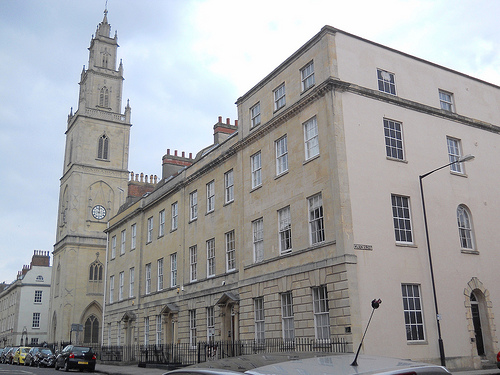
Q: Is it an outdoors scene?
A: Yes, it is outdoors.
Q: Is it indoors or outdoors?
A: It is outdoors.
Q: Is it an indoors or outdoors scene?
A: It is outdoors.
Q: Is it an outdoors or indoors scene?
A: It is outdoors.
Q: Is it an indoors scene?
A: No, it is outdoors.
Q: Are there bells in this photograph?
A: No, there are no bells.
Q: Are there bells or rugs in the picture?
A: No, there are no bells or rugs.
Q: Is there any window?
A: Yes, there is a window.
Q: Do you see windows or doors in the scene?
A: Yes, there is a window.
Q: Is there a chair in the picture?
A: No, there are no chairs.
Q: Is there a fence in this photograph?
A: Yes, there is a fence.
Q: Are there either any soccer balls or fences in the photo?
A: Yes, there is a fence.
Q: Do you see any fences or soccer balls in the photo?
A: Yes, there is a fence.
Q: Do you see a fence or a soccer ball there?
A: Yes, there is a fence.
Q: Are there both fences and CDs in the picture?
A: No, there is a fence but no cds.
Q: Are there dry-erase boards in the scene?
A: No, there are no dry-erase boards.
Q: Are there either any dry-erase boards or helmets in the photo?
A: No, there are no dry-erase boards or helmets.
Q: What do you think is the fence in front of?
A: The fence is in front of the building.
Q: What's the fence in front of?
A: The fence is in front of the building.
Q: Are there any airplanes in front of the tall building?
A: No, there is a fence in front of the building.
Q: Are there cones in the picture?
A: No, there are no cones.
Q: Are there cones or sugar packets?
A: No, there are no cones or sugar packets.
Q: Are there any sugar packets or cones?
A: No, there are no cones or sugar packets.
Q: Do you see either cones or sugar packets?
A: No, there are no cones or sugar packets.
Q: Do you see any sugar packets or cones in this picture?
A: No, there are no cones or sugar packets.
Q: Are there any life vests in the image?
A: No, there are no life vests.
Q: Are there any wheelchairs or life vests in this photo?
A: No, there are no life vests or wheelchairs.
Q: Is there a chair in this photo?
A: No, there are no chairs.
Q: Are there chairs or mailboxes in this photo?
A: No, there are no chairs or mailboxes.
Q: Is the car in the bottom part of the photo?
A: Yes, the car is in the bottom of the image.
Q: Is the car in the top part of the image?
A: No, the car is in the bottom of the image.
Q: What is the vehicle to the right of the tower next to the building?
A: The vehicle is a car.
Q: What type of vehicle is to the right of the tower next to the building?
A: The vehicle is a car.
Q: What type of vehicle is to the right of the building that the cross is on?
A: The vehicle is a car.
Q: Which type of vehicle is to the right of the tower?
A: The vehicle is a car.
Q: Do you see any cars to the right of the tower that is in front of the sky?
A: Yes, there is a car to the right of the tower.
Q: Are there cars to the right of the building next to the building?
A: Yes, there is a car to the right of the tower.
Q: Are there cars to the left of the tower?
A: No, the car is to the right of the tower.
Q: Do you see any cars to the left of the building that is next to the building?
A: No, the car is to the right of the tower.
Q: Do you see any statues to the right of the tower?
A: No, there is a car to the right of the tower.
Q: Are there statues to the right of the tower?
A: No, there is a car to the right of the tower.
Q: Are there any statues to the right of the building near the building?
A: No, there is a car to the right of the tower.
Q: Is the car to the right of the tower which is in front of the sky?
A: Yes, the car is to the right of the tower.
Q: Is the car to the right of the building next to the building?
A: Yes, the car is to the right of the tower.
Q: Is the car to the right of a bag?
A: No, the car is to the right of the tower.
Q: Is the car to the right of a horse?
A: No, the car is to the right of a vehicle.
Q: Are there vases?
A: No, there are no vases.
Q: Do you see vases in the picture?
A: No, there are no vases.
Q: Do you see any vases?
A: No, there are no vases.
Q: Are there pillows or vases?
A: No, there are no vases or pillows.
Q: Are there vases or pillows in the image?
A: No, there are no vases or pillows.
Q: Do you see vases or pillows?
A: No, there are no vases or pillows.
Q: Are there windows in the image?
A: Yes, there is a window.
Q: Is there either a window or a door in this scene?
A: Yes, there is a window.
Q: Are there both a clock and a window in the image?
A: Yes, there are both a window and a clock.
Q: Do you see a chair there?
A: No, there are no chairs.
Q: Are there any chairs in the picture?
A: No, there are no chairs.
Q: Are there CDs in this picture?
A: No, there are no cds.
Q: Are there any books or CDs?
A: No, there are no CDs or books.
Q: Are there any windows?
A: Yes, there is a window.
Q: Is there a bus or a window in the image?
A: Yes, there is a window.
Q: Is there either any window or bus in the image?
A: Yes, there is a window.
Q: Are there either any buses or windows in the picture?
A: Yes, there is a window.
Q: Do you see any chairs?
A: No, there are no chairs.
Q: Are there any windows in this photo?
A: Yes, there is a window.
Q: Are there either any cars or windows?
A: Yes, there is a window.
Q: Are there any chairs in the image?
A: No, there are no chairs.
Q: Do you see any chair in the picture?
A: No, there are no chairs.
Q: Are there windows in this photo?
A: Yes, there is a window.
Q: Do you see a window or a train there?
A: Yes, there is a window.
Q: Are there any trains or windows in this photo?
A: Yes, there is a window.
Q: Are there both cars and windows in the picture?
A: Yes, there are both a window and a car.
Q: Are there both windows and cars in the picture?
A: Yes, there are both a window and a car.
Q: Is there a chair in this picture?
A: No, there are no chairs.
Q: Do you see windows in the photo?
A: Yes, there is a window.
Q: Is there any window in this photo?
A: Yes, there is a window.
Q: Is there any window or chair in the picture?
A: Yes, there is a window.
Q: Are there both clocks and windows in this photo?
A: Yes, there are both a window and a clock.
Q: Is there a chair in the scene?
A: No, there are no chairs.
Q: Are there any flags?
A: No, there are no flags.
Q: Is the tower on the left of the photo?
A: Yes, the tower is on the left of the image.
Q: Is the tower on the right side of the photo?
A: No, the tower is on the left of the image.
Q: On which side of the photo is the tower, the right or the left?
A: The tower is on the left of the image.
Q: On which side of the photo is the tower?
A: The tower is on the left of the image.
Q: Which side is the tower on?
A: The tower is on the left of the image.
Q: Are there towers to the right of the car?
A: No, the tower is to the left of the car.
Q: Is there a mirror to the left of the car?
A: No, there is a tower to the left of the car.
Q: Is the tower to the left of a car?
A: Yes, the tower is to the left of a car.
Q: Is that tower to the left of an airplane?
A: No, the tower is to the left of a car.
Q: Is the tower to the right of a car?
A: No, the tower is to the left of a car.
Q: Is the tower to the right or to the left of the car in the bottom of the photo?
A: The tower is to the left of the car.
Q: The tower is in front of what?
A: The tower is in front of the sky.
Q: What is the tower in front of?
A: The tower is in front of the sky.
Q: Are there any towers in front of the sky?
A: Yes, there is a tower in front of the sky.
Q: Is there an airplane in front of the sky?
A: No, there is a tower in front of the sky.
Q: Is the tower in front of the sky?
A: Yes, the tower is in front of the sky.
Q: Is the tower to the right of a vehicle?
A: Yes, the tower is to the right of a vehicle.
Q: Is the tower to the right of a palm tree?
A: No, the tower is to the right of a vehicle.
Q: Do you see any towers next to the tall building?
A: Yes, there is a tower next to the building.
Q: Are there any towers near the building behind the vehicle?
A: Yes, there is a tower near the building.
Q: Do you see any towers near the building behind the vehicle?
A: Yes, there is a tower near the building.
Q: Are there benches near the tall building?
A: No, there is a tower near the building.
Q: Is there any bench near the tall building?
A: No, there is a tower near the building.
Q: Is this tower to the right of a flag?
A: No, the tower is to the right of a vehicle.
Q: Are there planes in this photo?
A: No, there are no planes.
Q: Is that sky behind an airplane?
A: No, the sky is behind the tower.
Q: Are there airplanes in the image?
A: No, there are no airplanes.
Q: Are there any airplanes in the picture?
A: No, there are no airplanes.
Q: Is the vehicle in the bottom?
A: Yes, the vehicle is in the bottom of the image.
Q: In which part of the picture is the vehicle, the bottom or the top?
A: The vehicle is in the bottom of the image.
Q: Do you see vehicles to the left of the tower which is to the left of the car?
A: Yes, there is a vehicle to the left of the tower.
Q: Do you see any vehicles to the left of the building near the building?
A: Yes, there is a vehicle to the left of the tower.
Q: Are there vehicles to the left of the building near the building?
A: Yes, there is a vehicle to the left of the tower.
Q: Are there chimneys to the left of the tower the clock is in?
A: No, there is a vehicle to the left of the tower.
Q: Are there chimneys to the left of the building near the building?
A: No, there is a vehicle to the left of the tower.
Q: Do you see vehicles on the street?
A: Yes, there is a vehicle on the street.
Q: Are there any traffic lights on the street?
A: No, there is a vehicle on the street.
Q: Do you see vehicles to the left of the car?
A: Yes, there is a vehicle to the left of the car.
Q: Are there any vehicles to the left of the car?
A: Yes, there is a vehicle to the left of the car.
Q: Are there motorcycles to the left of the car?
A: No, there is a vehicle to the left of the car.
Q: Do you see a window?
A: Yes, there is a window.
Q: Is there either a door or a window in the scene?
A: Yes, there is a window.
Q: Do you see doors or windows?
A: Yes, there is a window.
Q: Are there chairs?
A: No, there are no chairs.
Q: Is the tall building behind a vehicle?
A: Yes, the building is behind a vehicle.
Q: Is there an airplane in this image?
A: No, there are no airplanes.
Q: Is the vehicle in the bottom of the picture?
A: Yes, the vehicle is in the bottom of the image.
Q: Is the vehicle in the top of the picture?
A: No, the vehicle is in the bottom of the image.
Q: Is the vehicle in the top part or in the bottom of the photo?
A: The vehicle is in the bottom of the image.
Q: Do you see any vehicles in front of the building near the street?
A: Yes, there is a vehicle in front of the building.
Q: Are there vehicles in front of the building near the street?
A: Yes, there is a vehicle in front of the building.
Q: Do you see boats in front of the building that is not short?
A: No, there is a vehicle in front of the building.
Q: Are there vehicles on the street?
A: Yes, there is a vehicle on the street.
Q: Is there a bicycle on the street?
A: No, there is a vehicle on the street.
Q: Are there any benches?
A: No, there are no benches.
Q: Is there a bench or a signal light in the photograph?
A: No, there are no benches or traffic lights.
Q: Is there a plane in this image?
A: No, there are no airplanes.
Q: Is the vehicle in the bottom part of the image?
A: Yes, the vehicle is in the bottom of the image.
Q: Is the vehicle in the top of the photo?
A: No, the vehicle is in the bottom of the image.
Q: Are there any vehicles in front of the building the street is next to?
A: Yes, there is a vehicle in front of the building.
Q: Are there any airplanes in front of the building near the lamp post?
A: No, there is a vehicle in front of the building.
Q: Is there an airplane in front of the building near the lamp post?
A: No, there is a vehicle in front of the building.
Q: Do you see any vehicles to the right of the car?
A: No, the vehicle is to the left of the car.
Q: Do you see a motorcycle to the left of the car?
A: No, there is a vehicle to the left of the car.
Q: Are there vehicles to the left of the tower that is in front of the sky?
A: Yes, there is a vehicle to the left of the tower.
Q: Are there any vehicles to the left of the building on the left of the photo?
A: Yes, there is a vehicle to the left of the tower.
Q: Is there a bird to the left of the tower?
A: No, there is a vehicle to the left of the tower.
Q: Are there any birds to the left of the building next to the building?
A: No, there is a vehicle to the left of the tower.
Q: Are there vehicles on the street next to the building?
A: Yes, there is a vehicle on the street.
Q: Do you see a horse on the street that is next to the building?
A: No, there is a vehicle on the street.